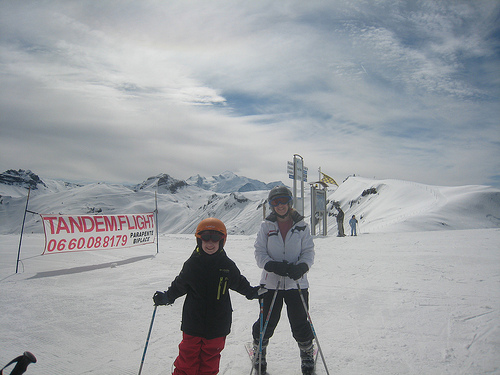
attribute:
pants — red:
[170, 330, 226, 373]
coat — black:
[162, 241, 258, 339]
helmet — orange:
[195, 216, 226, 255]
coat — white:
[254, 213, 316, 292]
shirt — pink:
[275, 217, 295, 242]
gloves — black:
[263, 260, 308, 281]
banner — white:
[16, 208, 158, 262]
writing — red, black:
[44, 215, 157, 254]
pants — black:
[251, 286, 313, 341]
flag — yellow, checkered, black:
[320, 171, 337, 188]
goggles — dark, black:
[267, 194, 289, 207]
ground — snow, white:
[3, 228, 498, 374]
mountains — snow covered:
[1, 167, 499, 235]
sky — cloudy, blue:
[1, 0, 500, 190]